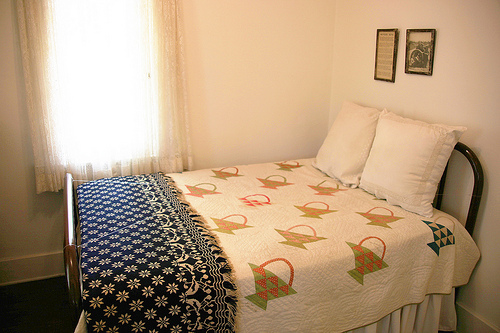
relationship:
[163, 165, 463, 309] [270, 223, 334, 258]
quilt has basket pattern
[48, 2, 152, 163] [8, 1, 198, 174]
sunlight streaming through window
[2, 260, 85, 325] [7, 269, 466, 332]
part of bedroom floor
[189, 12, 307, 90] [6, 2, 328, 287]
part of bedroom wall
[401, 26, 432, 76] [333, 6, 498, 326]
picture on wall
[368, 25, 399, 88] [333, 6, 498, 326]
picture on wall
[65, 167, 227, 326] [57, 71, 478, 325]
blanket covering bed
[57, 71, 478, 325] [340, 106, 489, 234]
bed has frame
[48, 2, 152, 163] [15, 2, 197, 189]
sunlight shining through curtains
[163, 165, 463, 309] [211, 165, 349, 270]
quilt has baskets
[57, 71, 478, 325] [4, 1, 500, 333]
bed in room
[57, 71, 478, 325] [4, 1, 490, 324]
bed in room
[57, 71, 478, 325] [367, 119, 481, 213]
bed has metal post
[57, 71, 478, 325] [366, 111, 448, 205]
bed has pillow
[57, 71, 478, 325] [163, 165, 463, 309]
bed has quilt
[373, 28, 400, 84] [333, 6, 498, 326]
picture on wall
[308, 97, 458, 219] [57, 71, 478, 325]
pillows on bed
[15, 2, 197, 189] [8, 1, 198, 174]
curtains covering window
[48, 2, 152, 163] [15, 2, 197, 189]
light shining through curtains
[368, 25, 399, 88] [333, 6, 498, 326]
frame on wall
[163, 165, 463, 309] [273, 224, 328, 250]
bedspread has basket pattern